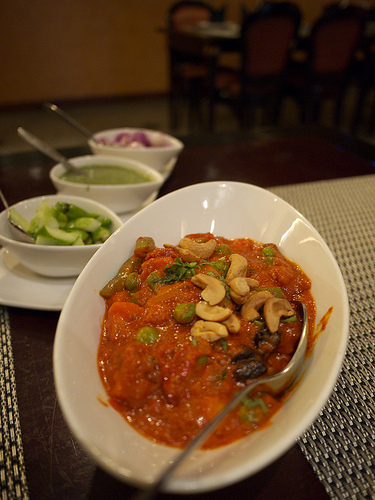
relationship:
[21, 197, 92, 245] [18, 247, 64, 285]
apples in bowl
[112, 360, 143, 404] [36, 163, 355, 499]
red sauce in bowl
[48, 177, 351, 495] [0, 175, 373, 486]
bowl on table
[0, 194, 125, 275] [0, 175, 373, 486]
bowl on table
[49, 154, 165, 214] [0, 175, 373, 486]
bowl on table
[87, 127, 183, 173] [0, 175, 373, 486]
bowl on table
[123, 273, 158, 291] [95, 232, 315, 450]
peas in a sauce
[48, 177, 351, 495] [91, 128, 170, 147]
bowl has something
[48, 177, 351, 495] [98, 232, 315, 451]
bowl of soup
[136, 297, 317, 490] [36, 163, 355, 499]
spoon in a bowl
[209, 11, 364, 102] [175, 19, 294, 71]
chairs around a table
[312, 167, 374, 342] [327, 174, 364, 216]
table has mat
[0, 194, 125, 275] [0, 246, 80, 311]
bowl on dish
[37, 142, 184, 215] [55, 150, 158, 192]
bowl has guacamole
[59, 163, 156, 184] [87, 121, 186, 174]
guacamole in dish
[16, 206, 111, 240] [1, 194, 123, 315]
chunks in dish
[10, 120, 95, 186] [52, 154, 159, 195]
spoon in sauce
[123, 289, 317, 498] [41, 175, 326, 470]
spoon in dish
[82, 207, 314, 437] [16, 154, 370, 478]
food in bowl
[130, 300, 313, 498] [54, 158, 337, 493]
spoon in bowl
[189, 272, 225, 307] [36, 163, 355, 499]
cashew in bowl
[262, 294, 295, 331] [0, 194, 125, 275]
cashew in bowl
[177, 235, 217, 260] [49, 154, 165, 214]
cashew in bowl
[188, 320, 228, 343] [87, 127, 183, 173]
cashew in bowl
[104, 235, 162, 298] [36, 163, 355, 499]
vegetables in bowl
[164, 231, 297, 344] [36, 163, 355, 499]
nuts in bowl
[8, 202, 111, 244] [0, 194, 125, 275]
veggies in bowl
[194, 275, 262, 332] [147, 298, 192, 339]
cashews next to pea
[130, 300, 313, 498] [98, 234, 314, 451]
spoon inside soup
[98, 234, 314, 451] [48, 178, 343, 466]
soup inside bowl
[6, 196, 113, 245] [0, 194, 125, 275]
apples inside bowl